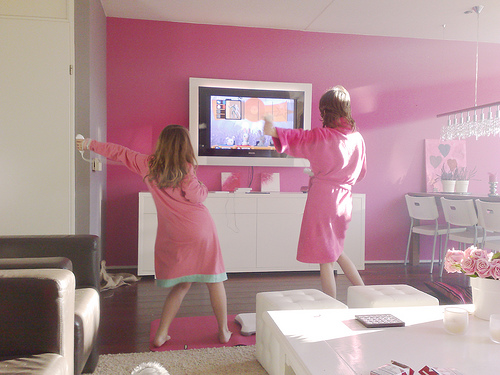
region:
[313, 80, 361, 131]
the head of the woman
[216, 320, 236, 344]
the foot of the girl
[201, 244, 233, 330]
the leg of the girl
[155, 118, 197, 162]
the head of the girl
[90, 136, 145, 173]
the arm of the girl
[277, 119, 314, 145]
the arm of the woman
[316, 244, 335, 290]
the leg of the woman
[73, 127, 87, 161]
a white game controller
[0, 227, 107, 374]
a brown armchair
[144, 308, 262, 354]
a pink rug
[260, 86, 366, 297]
Young lady playing video game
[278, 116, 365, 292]
Pink robe on girl playing game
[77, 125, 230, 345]
Young girl playing video game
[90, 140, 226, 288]
Pink robe with gray fringe on young girl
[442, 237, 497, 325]
White flower pot of pink roses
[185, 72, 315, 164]
Flat screen television in living room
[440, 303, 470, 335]
Drinking glass on table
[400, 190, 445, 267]
White chair at counter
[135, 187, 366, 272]
White living room cabinet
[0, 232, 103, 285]
Brown leather chair in living room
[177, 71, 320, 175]
a flat screen television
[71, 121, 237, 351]
a girl in a pink robe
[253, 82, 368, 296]
a girl in a pink robe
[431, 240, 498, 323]
a white pot with pink roses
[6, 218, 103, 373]
brown leather chairs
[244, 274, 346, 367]
a white cube seat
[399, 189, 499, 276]
three white chairs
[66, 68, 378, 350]
two girls playing a video game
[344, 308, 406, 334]
a black remote control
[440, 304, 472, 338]
a clear votive candle holder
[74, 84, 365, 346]
Two girls playing video games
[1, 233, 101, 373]
a pair of brown couches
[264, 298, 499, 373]
a white coffee table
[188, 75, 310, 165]
a television on the wall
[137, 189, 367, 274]
a cabinet under the television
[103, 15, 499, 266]
a wall that is painted pink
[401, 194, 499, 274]
a row of white chairs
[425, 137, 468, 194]
a pink painting against the wall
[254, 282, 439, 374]
a set of white stools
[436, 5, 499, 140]
a decorative lamp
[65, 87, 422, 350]
two young girls in pink robes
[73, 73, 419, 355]
two girls playing wii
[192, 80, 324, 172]
flat screen television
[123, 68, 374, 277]
television on a white entertainment center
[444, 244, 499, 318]
white planter with big pink roses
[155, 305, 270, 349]
pink floor mat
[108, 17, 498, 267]
bright pink accent wall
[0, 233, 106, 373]
two brown armchairs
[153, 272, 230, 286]
mint green trim on the bottom of the pink robe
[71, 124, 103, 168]
hand holding the wii controller